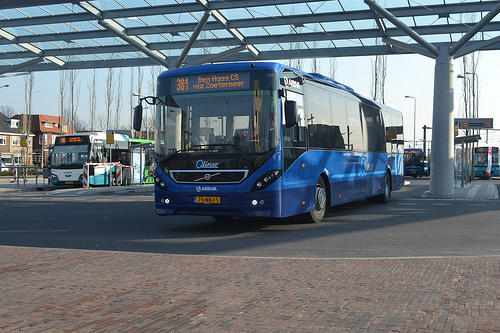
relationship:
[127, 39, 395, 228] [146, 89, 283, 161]
bus has windshield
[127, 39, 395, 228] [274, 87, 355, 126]
bus has window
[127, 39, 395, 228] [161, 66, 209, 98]
bus has number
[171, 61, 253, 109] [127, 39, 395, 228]
sign on bus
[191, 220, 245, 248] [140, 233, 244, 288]
shadow on ground